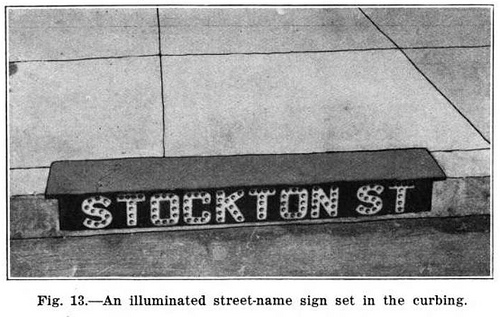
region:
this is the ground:
[86, 34, 326, 112]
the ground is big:
[5, 12, 469, 143]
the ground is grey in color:
[266, 16, 434, 113]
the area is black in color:
[62, 162, 364, 179]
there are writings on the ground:
[81, 188, 417, 210]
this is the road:
[306, 240, 459, 273]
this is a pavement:
[226, 17, 425, 96]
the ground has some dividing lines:
[128, 22, 473, 122]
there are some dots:
[258, 187, 267, 221]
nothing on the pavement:
[254, 25, 398, 98]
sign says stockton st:
[72, 152, 437, 232]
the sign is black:
[46, 140, 452, 270]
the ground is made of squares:
[6, 5, 491, 231]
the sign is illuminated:
[85, 155, 461, 240]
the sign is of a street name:
[75, 170, 470, 236]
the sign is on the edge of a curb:
[44, 136, 497, 274]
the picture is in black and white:
[5, 3, 495, 276]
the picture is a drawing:
[7, 5, 479, 255]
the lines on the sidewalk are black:
[7, 8, 497, 191]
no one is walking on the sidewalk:
[6, 5, 450, 174]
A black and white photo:
[37, 41, 472, 248]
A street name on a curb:
[36, 64, 456, 256]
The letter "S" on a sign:
[71, 178, 114, 246]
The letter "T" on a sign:
[116, 176, 146, 244]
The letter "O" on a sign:
[148, 181, 179, 242]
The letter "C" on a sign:
[183, 183, 210, 242]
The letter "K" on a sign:
[213, 178, 245, 237]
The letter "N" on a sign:
[309, 173, 340, 235]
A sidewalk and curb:
[87, 22, 463, 233]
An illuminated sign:
[45, 162, 438, 242]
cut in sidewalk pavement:
[7, 42, 497, 64]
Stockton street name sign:
[64, 181, 435, 233]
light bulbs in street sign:
[85, 181, 422, 231]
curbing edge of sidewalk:
[12, 147, 499, 217]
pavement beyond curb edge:
[5, 210, 482, 300]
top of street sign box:
[50, 146, 467, 186]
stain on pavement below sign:
[275, 213, 490, 248]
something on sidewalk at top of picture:
[265, 8, 290, 23]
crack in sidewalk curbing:
[0, 192, 54, 211]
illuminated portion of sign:
[67, 180, 447, 225]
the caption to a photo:
[27, 289, 476, 310]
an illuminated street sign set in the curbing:
[33, 145, 457, 231]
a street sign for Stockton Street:
[39, 132, 454, 246]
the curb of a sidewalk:
[9, 147, 498, 253]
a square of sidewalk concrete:
[119, 33, 498, 213]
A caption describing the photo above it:
[34, 288, 470, 314]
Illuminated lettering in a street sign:
[75, 186, 347, 227]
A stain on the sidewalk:
[4, 51, 28, 81]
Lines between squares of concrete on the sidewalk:
[110, 28, 245, 109]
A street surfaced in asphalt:
[189, 188, 467, 285]